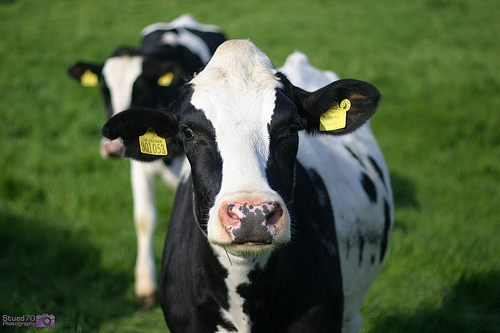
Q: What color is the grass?
A: Green.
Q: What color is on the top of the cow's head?
A: White.